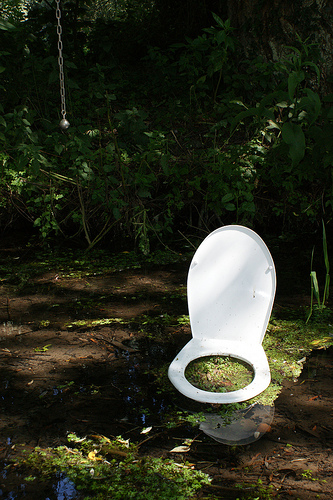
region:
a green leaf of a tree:
[214, 191, 230, 200]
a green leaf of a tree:
[242, 201, 258, 215]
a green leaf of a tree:
[113, 210, 119, 221]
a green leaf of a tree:
[121, 196, 127, 205]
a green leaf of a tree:
[57, 146, 64, 155]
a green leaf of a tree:
[111, 203, 124, 226]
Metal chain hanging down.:
[42, 1, 82, 140]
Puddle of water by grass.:
[10, 464, 87, 499]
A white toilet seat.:
[160, 339, 275, 408]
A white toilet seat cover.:
[179, 223, 286, 343]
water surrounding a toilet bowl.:
[102, 373, 331, 453]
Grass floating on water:
[23, 437, 218, 493]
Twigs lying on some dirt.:
[26, 331, 143, 377]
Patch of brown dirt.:
[34, 282, 160, 307]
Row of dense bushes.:
[15, 131, 310, 209]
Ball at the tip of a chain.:
[49, 118, 80, 135]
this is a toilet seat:
[153, 327, 280, 415]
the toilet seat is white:
[154, 319, 279, 425]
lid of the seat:
[173, 213, 285, 348]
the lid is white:
[176, 209, 279, 340]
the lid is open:
[166, 217, 285, 410]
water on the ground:
[38, 285, 327, 498]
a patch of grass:
[0, 412, 216, 496]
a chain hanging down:
[39, 2, 97, 138]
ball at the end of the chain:
[49, 105, 75, 126]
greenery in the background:
[10, 8, 328, 256]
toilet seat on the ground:
[3, 131, 330, 498]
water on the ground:
[47, 314, 332, 464]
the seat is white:
[168, 317, 281, 415]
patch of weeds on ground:
[22, 413, 206, 498]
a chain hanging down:
[26, 4, 110, 137]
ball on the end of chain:
[56, 110, 71, 131]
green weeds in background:
[13, 15, 323, 266]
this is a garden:
[28, 75, 272, 438]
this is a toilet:
[144, 258, 252, 373]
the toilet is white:
[179, 277, 314, 454]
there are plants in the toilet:
[175, 321, 250, 404]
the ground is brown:
[16, 293, 107, 361]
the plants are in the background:
[38, 105, 235, 287]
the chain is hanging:
[43, 52, 84, 126]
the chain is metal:
[43, 92, 103, 162]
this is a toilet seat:
[163, 325, 278, 416]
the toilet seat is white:
[167, 329, 270, 408]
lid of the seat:
[177, 217, 292, 336]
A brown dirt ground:
[18, 258, 327, 499]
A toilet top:
[144, 265, 279, 409]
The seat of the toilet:
[154, 340, 272, 413]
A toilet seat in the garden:
[160, 335, 267, 406]